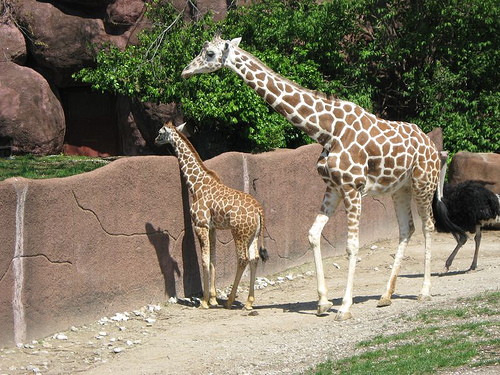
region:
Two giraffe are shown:
[152, 21, 434, 326]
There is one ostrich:
[434, 136, 499, 289]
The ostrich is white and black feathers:
[435, 144, 499, 276]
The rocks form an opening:
[1, 0, 233, 159]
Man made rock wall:
[0, 126, 499, 349]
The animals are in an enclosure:
[4, 130, 496, 373]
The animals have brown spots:
[153, 32, 443, 323]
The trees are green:
[1, 0, 498, 156]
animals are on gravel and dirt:
[0, 225, 499, 371]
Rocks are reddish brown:
[3, 0, 126, 157]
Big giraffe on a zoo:
[168, 31, 456, 326]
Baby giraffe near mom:
[148, 116, 276, 327]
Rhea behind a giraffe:
[430, 130, 495, 280]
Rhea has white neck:
[435, 146, 497, 274]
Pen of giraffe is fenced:
[0, 123, 451, 338]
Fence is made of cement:
[11, 145, 443, 345]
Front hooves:
[315, 296, 356, 328]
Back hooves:
[373, 288, 432, 313]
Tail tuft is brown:
[253, 241, 270, 269]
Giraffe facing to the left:
[145, 108, 276, 319]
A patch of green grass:
[369, 329, 476, 372]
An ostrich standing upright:
[442, 150, 499, 261]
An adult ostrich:
[177, 28, 432, 118]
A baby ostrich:
[155, 117, 271, 317]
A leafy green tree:
[96, 46, 177, 97]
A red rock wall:
[3, 173, 158, 295]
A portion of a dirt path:
[167, 325, 261, 366]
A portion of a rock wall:
[0, 0, 81, 160]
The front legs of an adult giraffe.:
[304, 184, 362, 320]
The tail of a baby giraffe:
[248, 204, 271, 282]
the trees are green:
[280, 40, 459, 115]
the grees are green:
[342, 328, 460, 373]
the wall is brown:
[25, 190, 182, 300]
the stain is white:
[12, 197, 40, 353]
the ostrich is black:
[443, 162, 498, 248]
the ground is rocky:
[102, 314, 267, 359]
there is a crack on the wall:
[65, 192, 187, 244]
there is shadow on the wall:
[132, 212, 202, 288]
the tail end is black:
[255, 245, 284, 268]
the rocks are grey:
[11, 71, 57, 98]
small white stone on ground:
[137, 313, 164, 328]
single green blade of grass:
[311, 347, 341, 373]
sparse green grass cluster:
[377, 341, 485, 373]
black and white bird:
[437, 143, 499, 261]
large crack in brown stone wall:
[20, 157, 172, 265]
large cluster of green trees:
[117, 34, 382, 109]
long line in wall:
[11, 189, 68, 354]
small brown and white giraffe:
[152, 121, 292, 278]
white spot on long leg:
[289, 215, 353, 268]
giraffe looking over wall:
[164, 34, 353, 126]